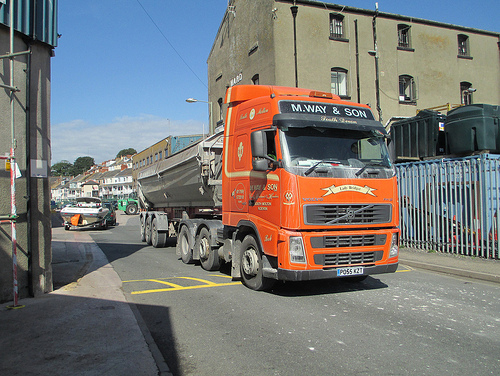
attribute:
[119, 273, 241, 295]
lines — yellow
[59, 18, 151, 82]
sky — blue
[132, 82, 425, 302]
truck — Orange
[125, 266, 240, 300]
lines — yellow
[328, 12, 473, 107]
windows — glass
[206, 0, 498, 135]
building — three-story, cement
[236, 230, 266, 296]
tire — Heavy-duty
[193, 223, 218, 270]
tire — Heavy-duty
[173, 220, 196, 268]
tire — Heavy-duty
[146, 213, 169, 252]
tire — Heavy-duty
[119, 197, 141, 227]
tire — Heavy-duty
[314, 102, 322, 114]
letter — white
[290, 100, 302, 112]
letter — white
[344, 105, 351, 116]
letter — white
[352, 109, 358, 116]
letter — white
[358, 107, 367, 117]
letter — white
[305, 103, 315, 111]
letter — white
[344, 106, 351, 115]
letter — white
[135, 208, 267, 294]
tires — Six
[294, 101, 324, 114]
letter — white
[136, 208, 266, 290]
wheels — six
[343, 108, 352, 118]
letter — white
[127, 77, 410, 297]
truck — orange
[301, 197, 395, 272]
vents — three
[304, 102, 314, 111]
letter — white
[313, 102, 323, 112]
letter — white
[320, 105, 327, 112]
letter — white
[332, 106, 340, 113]
letter — white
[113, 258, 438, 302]
crosswalk — yellow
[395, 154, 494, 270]
fence — Metal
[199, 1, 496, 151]
building — Brown 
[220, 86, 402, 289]
cab — orange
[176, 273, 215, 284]
line — yellow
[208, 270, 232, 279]
line — yellow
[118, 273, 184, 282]
line — yellow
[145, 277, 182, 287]
line — yellow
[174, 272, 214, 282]
line — yellow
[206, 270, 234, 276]
line — yellow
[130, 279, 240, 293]
line — yellow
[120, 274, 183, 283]
line — yellow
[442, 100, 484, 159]
bin — big, black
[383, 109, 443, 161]
bin — big, black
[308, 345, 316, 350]
spot — white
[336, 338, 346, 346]
spot — white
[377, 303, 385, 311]
spot — white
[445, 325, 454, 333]
spot — white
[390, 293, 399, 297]
spot — white